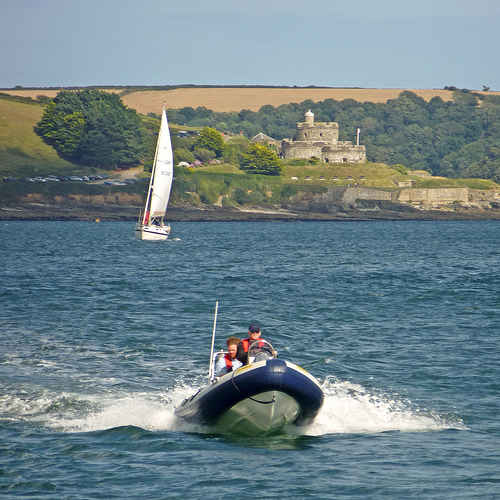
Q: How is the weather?
A: It is cloudless.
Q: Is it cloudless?
A: Yes, it is cloudless.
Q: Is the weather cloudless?
A: Yes, it is cloudless.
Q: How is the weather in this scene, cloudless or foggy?
A: It is cloudless.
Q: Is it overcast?
A: No, it is cloudless.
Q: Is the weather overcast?
A: No, it is cloudless.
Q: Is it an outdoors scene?
A: Yes, it is outdoors.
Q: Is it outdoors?
A: Yes, it is outdoors.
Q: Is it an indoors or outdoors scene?
A: It is outdoors.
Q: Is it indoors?
A: No, it is outdoors.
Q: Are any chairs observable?
A: No, there are no chairs.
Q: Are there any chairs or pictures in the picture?
A: No, there are no chairs or pictures.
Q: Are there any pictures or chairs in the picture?
A: No, there are no chairs or pictures.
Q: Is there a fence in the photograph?
A: No, there are no fences.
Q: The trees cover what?
A: The trees cover the hills.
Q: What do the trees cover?
A: The trees cover the hills.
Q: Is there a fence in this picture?
A: No, there are no fences.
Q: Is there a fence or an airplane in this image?
A: No, there are no fences or airplanes.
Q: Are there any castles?
A: Yes, there is a castle.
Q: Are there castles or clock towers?
A: Yes, there is a castle.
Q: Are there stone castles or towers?
A: Yes, there is a stone castle.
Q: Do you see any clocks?
A: No, there are no clocks.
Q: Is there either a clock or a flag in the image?
A: No, there are no clocks or flags.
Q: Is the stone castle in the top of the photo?
A: Yes, the castle is in the top of the image.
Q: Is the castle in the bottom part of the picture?
A: No, the castle is in the top of the image.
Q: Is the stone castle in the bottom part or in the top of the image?
A: The castle is in the top of the image.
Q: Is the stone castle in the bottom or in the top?
A: The castle is in the top of the image.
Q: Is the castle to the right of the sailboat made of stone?
A: Yes, the castle is made of stone.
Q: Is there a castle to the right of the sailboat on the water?
A: Yes, there is a castle to the right of the sailboat.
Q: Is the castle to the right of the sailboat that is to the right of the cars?
A: Yes, the castle is to the right of the sailboat.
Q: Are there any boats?
A: Yes, there is a boat.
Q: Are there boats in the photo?
A: Yes, there is a boat.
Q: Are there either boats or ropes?
A: Yes, there is a boat.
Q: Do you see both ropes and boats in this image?
A: No, there is a boat but no ropes.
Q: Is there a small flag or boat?
A: Yes, there is a small boat.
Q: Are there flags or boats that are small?
A: Yes, the boat is small.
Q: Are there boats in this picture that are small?
A: Yes, there is a small boat.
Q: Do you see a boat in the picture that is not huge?
A: Yes, there is a small boat.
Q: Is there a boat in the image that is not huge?
A: Yes, there is a small boat.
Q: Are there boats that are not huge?
A: Yes, there is a small boat.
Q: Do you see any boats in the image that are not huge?
A: Yes, there is a small boat.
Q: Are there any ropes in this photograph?
A: No, there are no ropes.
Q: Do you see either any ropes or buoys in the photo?
A: No, there are no ropes or buoys.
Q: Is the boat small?
A: Yes, the boat is small.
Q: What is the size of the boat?
A: The boat is small.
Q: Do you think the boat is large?
A: No, the boat is small.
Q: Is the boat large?
A: No, the boat is small.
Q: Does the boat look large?
A: No, the boat is small.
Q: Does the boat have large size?
A: No, the boat is small.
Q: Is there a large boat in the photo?
A: No, there is a boat but it is small.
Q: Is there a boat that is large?
A: No, there is a boat but it is small.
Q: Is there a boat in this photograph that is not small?
A: No, there is a boat but it is small.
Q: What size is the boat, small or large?
A: The boat is small.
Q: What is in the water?
A: The boat is in the water.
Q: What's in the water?
A: The boat is in the water.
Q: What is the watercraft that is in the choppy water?
A: The watercraft is a boat.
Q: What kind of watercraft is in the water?
A: The watercraft is a boat.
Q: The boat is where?
A: The boat is in the water.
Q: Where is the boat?
A: The boat is in the water.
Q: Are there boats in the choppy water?
A: Yes, there is a boat in the water.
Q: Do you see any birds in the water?
A: No, there is a boat in the water.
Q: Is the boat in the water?
A: Yes, the boat is in the water.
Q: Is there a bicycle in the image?
A: No, there are no bicycles.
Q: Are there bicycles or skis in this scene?
A: No, there are no bicycles or skis.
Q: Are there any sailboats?
A: Yes, there is a sailboat.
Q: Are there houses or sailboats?
A: Yes, there is a sailboat.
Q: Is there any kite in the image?
A: No, there are no kites.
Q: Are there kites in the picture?
A: No, there are no kites.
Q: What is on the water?
A: The sailboat is on the water.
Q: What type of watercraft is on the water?
A: The watercraft is a sailboat.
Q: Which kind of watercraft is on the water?
A: The watercraft is a sailboat.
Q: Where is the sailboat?
A: The sailboat is on the water.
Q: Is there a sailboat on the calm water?
A: Yes, there is a sailboat on the water.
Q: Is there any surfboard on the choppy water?
A: No, there is a sailboat on the water.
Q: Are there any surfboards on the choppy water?
A: No, there is a sailboat on the water.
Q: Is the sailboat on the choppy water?
A: Yes, the sailboat is on the water.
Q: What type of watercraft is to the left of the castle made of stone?
A: The watercraft is a sailboat.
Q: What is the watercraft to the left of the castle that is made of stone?
A: The watercraft is a sailboat.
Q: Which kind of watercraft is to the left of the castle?
A: The watercraft is a sailboat.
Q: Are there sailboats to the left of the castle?
A: Yes, there is a sailboat to the left of the castle.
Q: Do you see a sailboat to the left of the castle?
A: Yes, there is a sailboat to the left of the castle.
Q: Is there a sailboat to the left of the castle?
A: Yes, there is a sailboat to the left of the castle.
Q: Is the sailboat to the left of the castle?
A: Yes, the sailboat is to the left of the castle.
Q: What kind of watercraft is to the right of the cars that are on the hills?
A: The watercraft is a sailboat.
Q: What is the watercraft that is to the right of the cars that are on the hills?
A: The watercraft is a sailboat.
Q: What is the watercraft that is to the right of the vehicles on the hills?
A: The watercraft is a sailboat.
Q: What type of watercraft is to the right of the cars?
A: The watercraft is a sailboat.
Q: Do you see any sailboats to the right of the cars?
A: Yes, there is a sailboat to the right of the cars.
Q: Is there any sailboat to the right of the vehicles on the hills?
A: Yes, there is a sailboat to the right of the cars.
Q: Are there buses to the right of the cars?
A: No, there is a sailboat to the right of the cars.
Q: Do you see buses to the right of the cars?
A: No, there is a sailboat to the right of the cars.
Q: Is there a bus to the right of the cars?
A: No, there is a sailboat to the right of the cars.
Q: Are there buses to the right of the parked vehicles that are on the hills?
A: No, there is a sailboat to the right of the cars.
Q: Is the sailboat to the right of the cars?
A: Yes, the sailboat is to the right of the cars.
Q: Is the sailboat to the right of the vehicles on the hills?
A: Yes, the sailboat is to the right of the cars.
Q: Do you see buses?
A: No, there are no buses.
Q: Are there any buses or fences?
A: No, there are no buses or fences.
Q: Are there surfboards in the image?
A: No, there are no surfboards.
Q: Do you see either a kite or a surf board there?
A: No, there are no surfboards or kites.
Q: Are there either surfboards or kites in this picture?
A: No, there are no surfboards or kites.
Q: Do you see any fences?
A: No, there are no fences.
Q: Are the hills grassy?
A: Yes, the hills are grassy.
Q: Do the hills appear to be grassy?
A: Yes, the hills are grassy.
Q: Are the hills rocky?
A: No, the hills are grassy.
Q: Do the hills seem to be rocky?
A: No, the hills are grassy.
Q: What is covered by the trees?
A: The hills are covered by the trees.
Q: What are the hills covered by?
A: The hills are covered by the trees.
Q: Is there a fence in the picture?
A: No, there are no fences.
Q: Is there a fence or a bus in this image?
A: No, there are no fences or buses.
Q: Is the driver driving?
A: Yes, the driver is driving.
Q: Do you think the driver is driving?
A: Yes, the driver is driving.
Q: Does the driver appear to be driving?
A: Yes, the driver is driving.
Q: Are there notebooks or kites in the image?
A: No, there are no kites or notebooks.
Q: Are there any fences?
A: No, there are no fences.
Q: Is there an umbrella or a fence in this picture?
A: No, there are no fences or umbrellas.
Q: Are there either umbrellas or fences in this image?
A: No, there are no fences or umbrellas.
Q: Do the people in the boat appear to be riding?
A: Yes, the people are riding.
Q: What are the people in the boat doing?
A: The people are riding.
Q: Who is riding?
A: The people are riding.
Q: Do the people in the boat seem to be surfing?
A: No, the people are riding.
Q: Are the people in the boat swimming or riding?
A: The people are riding.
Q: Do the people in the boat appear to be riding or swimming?
A: The people are riding.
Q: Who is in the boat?
A: The people are in the boat.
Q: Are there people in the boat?
A: Yes, there are people in the boat.